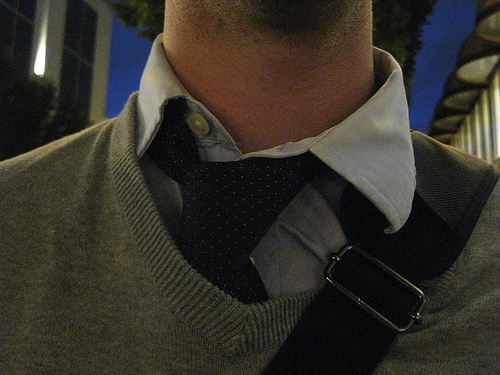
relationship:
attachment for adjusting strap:
[332, 244, 499, 318] [298, 153, 480, 353]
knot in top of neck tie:
[155, 132, 341, 256] [142, 106, 326, 302]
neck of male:
[163, 0, 377, 152] [0, 3, 498, 373]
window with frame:
[60, 2, 96, 122] [30, 3, 110, 129]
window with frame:
[0, 0, 96, 166] [30, 3, 110, 129]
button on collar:
[187, 110, 210, 134] [135, 31, 416, 232]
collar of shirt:
[135, 31, 416, 232] [137, 30, 424, 287]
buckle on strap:
[324, 243, 426, 333] [257, 120, 497, 364]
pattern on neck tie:
[186, 172, 263, 217] [153, 106, 315, 303]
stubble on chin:
[259, 3, 349, 57] [268, 3, 342, 13]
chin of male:
[268, 3, 342, 13] [0, 0, 500, 375]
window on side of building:
[0, 0, 96, 166] [0, 1, 497, 162]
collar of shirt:
[135, 31, 416, 232] [130, 27, 490, 276]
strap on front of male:
[259, 163, 499, 374] [0, 0, 500, 375]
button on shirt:
[182, 110, 229, 155] [137, 30, 424, 287]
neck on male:
[163, 0, 373, 152] [0, 0, 500, 375]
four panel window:
[14, 50, 104, 120] [61, 1, 97, 138]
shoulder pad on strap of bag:
[28, 128, 78, 263] [344, 208, 471, 367]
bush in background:
[1, 55, 88, 158] [36, 53, 109, 145]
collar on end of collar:
[135, 31, 416, 235] [376, 190, 415, 237]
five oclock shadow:
[52, 50, 108, 145] [252, 0, 372, 50]